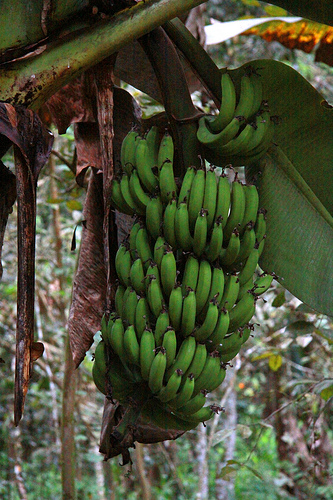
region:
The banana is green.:
[240, 173, 259, 235]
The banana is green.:
[225, 170, 246, 234]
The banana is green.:
[214, 161, 233, 233]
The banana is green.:
[200, 165, 219, 233]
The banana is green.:
[186, 163, 208, 228]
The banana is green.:
[175, 157, 198, 216]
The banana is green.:
[189, 200, 210, 258]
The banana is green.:
[207, 207, 225, 268]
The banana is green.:
[172, 194, 195, 255]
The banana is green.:
[142, 193, 164, 250]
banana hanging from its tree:
[99, 24, 259, 341]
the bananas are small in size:
[130, 177, 231, 432]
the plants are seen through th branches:
[237, 428, 293, 496]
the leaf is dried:
[71, 160, 126, 279]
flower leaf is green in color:
[288, 179, 330, 238]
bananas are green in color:
[148, 237, 210, 346]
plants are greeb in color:
[234, 441, 290, 486]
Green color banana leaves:
[280, 134, 330, 220]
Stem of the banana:
[151, 48, 197, 120]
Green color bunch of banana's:
[127, 142, 222, 359]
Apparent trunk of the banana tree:
[0, 31, 41, 157]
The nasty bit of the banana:
[177, 366, 192, 381]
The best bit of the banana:
[124, 350, 155, 390]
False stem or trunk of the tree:
[65, 0, 157, 54]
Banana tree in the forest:
[9, 4, 332, 495]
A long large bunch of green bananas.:
[93, 122, 276, 445]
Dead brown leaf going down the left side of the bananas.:
[67, 85, 118, 369]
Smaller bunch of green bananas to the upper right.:
[192, 67, 280, 165]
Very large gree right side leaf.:
[206, 68, 332, 318]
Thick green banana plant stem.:
[135, 30, 200, 169]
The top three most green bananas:
[211, 66, 263, 133]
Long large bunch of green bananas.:
[91, 66, 277, 440]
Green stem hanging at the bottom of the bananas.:
[113, 383, 149, 440]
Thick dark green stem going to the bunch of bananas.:
[139, 36, 207, 170]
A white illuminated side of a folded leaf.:
[200, 15, 304, 46]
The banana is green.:
[199, 67, 239, 134]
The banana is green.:
[195, 114, 243, 151]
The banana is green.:
[133, 136, 163, 197]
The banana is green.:
[156, 155, 181, 207]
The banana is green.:
[127, 167, 158, 212]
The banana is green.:
[214, 164, 234, 242]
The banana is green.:
[188, 204, 207, 267]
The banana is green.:
[155, 238, 179, 305]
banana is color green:
[195, 111, 241, 150]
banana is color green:
[180, 404, 222, 427]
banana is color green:
[147, 346, 163, 403]